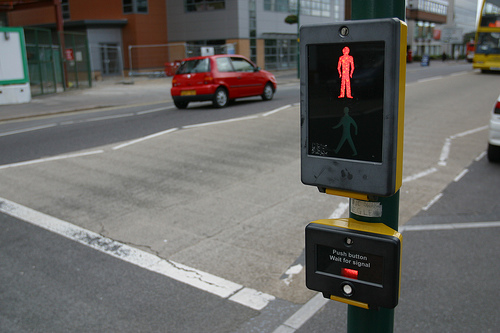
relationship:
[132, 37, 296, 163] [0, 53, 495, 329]
car on street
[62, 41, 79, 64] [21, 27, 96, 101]
red sign on fence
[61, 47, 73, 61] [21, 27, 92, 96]
sign on fence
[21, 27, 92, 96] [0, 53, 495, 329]
fence across street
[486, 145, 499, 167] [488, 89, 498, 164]
tire of vehicle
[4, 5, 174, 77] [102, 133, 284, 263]
bulding along street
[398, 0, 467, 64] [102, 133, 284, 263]
bulding along street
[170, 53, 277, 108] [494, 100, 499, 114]
car with taillight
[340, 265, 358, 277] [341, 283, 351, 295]
red light above white button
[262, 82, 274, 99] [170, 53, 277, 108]
tire of car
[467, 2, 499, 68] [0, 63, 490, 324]
bus on road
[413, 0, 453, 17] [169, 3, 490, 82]
windows on building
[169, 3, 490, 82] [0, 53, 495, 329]
building across street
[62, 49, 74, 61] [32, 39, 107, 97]
sign on gate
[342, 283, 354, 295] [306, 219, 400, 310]
button on machine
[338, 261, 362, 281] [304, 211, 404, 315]
light on machine